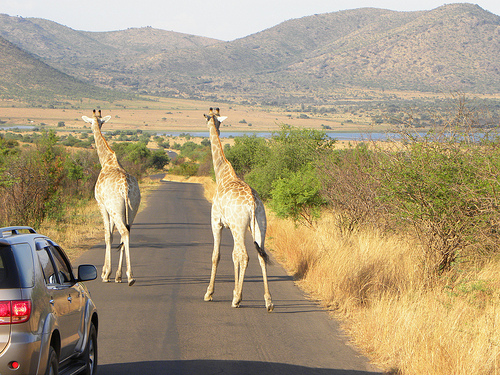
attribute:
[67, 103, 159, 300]
giraffe — walking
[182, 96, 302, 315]
giraffe — walking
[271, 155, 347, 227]
plant — green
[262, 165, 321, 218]
bush — small, green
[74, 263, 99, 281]
mirror — side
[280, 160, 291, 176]
leaf — green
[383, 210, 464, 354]
grass — dry, brittle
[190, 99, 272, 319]
giraffe — light colored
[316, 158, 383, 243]
tree — bare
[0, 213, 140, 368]
vehicle — gray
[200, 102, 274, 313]
giraffe — first 